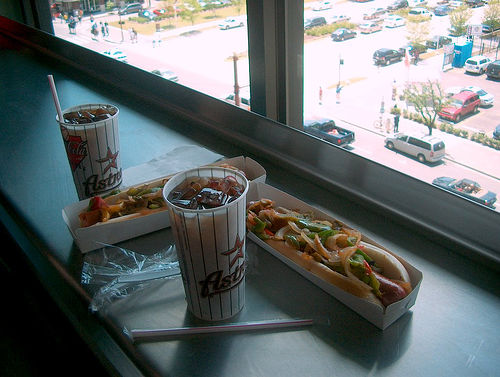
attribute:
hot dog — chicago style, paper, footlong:
[247, 189, 420, 317]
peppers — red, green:
[298, 218, 337, 245]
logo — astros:
[81, 162, 125, 192]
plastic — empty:
[76, 240, 192, 317]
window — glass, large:
[21, 2, 499, 209]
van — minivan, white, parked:
[381, 124, 455, 168]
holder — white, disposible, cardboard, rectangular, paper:
[242, 176, 424, 328]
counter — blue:
[1, 44, 499, 370]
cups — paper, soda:
[58, 104, 248, 327]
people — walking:
[378, 105, 405, 136]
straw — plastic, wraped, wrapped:
[123, 316, 325, 337]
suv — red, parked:
[439, 85, 480, 126]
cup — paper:
[163, 161, 261, 324]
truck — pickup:
[307, 112, 359, 147]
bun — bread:
[251, 197, 402, 299]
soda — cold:
[160, 165, 248, 220]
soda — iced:
[61, 105, 110, 127]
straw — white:
[44, 70, 72, 131]